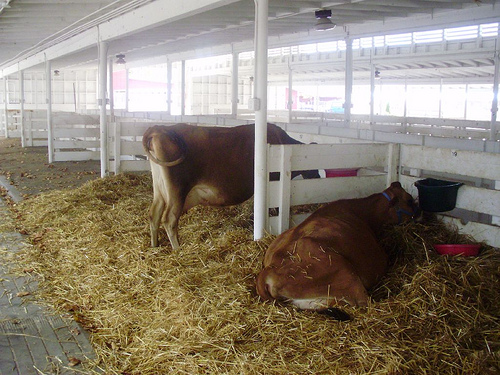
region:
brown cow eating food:
[132, 109, 327, 261]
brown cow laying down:
[248, 165, 435, 328]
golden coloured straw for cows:
[12, 159, 498, 374]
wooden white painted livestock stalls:
[0, 4, 498, 255]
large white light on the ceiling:
[310, 7, 340, 36]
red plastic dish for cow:
[430, 232, 485, 257]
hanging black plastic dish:
[409, 159, 466, 214]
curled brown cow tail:
[135, 120, 188, 175]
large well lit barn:
[5, 4, 499, 370]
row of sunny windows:
[273, 65, 498, 124]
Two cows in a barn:
[86, 102, 443, 321]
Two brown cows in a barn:
[88, 54, 452, 351]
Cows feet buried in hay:
[229, 194, 407, 346]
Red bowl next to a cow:
[303, 174, 498, 269]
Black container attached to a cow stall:
[365, 143, 492, 216]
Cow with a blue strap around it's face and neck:
[334, 165, 420, 257]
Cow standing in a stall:
[26, 10, 363, 260]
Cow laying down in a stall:
[257, 141, 465, 345]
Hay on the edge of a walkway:
[1, 162, 108, 373]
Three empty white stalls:
[0, 77, 137, 196]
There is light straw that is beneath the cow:
[136, 272, 161, 340]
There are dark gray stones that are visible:
[23, 105, 55, 312]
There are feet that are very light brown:
[155, 235, 177, 253]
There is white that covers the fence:
[290, 137, 304, 180]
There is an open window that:
[443, 83, 470, 138]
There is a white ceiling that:
[36, 13, 70, 60]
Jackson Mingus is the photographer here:
[112, 20, 360, 335]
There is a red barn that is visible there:
[113, 68, 128, 90]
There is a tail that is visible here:
[136, 121, 173, 172]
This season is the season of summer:
[91, 85, 317, 367]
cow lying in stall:
[268, 180, 430, 306]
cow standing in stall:
[118, 121, 296, 224]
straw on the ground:
[86, 260, 241, 297]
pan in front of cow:
[435, 240, 482, 260]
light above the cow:
[306, 6, 345, 36]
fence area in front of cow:
[399, 143, 499, 225]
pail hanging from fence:
[413, 170, 460, 217]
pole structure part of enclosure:
[85, 55, 118, 189]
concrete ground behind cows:
[3, 277, 80, 369]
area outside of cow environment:
[295, 87, 472, 118]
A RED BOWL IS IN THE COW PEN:
[438, 220, 479, 275]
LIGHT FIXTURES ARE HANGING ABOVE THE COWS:
[306, 10, 361, 32]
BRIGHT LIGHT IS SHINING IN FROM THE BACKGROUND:
[125, 76, 480, 126]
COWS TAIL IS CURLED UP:
[127, 125, 202, 166]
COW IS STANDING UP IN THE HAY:
[130, 120, 350, 240]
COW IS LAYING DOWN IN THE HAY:
[236, 170, 411, 321]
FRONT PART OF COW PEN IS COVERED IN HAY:
[35, 175, 495, 370]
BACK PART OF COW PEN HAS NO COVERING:
[0, 102, 137, 197]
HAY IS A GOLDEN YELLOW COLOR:
[115, 252, 260, 352]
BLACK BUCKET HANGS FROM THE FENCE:
[416, 171, 476, 220]